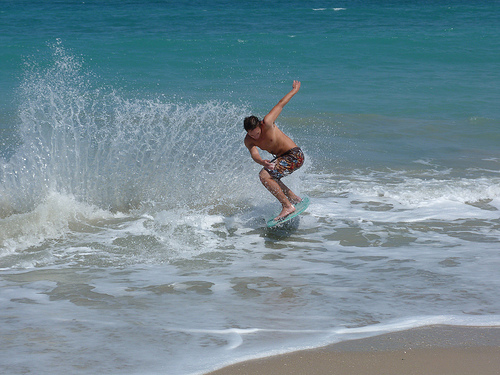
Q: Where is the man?
A: At the beach.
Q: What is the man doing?
A: Surfing.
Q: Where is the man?
A: In the water.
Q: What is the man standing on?
A: A surfboard.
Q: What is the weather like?
A: Sunny.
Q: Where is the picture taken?
A: At a beach.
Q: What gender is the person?
A: A male.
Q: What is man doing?
A: Surfing.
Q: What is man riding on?
A: Surfboard.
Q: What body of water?
A: Ocean.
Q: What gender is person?
A: Male.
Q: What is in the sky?
A: Clouds.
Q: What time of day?
A: During the afternoon.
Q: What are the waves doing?
A: Crashing.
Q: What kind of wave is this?
A: Sheet.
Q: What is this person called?
A: Surfer.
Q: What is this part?
A: Edge of water.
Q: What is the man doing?
A: He is surfing.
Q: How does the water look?
A: It is blue.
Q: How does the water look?
A: It is deep blue.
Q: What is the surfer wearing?
A: Blue and brown trunks.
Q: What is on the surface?
A: White foam.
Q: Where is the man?
A: In the ocean.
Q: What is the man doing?
A: Surfing in the ocean.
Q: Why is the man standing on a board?
A: He is surfing.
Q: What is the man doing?
A: Surfing.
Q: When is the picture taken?
A: Daytime.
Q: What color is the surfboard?
A: Blue green.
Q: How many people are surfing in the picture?
A: One.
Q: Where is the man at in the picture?
A: On the wave.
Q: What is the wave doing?
A: Heading for the shore.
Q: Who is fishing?
A: No one.